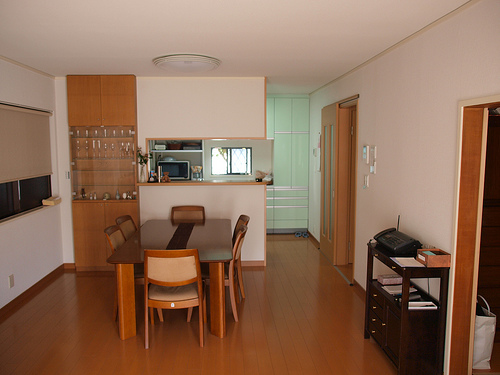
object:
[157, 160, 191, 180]
microwave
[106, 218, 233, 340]
table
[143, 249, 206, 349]
chair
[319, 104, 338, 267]
door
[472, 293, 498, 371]
bag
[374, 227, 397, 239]
phone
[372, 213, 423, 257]
answering machine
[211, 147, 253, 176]
window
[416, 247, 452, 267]
box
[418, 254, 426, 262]
label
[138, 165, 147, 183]
vase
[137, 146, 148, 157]
flower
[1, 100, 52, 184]
shade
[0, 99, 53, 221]
window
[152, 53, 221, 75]
light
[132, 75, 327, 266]
kitchen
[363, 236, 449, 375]
table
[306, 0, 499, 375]
wall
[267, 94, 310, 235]
wall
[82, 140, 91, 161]
glasses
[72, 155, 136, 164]
shelves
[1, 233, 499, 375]
floor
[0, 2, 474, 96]
ceiling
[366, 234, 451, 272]
shelf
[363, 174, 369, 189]
switches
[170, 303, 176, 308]
spot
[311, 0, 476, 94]
edge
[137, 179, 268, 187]
counter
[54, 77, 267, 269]
wall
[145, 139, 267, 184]
opening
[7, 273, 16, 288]
outlet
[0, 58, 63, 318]
wall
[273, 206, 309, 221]
tile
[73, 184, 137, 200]
bar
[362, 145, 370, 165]
frames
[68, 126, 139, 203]
cabinets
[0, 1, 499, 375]
room